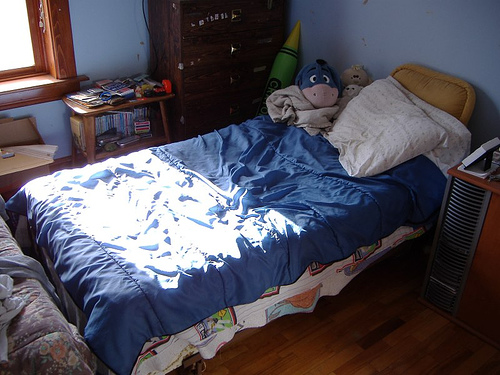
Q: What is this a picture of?
A: Bedroom.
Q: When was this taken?
A: Daytime.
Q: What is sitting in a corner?
A: A crayon.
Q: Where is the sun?
A: Shining on the bed.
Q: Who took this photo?
A: The owner.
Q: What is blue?
A: The comforter.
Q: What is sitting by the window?
A: A box.